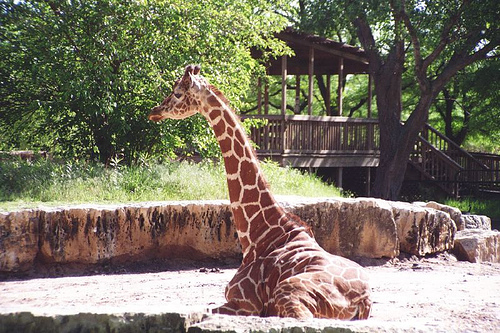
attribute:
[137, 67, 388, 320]
giraffe — down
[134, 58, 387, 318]
ground — brown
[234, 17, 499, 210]
gazebo — giraffe